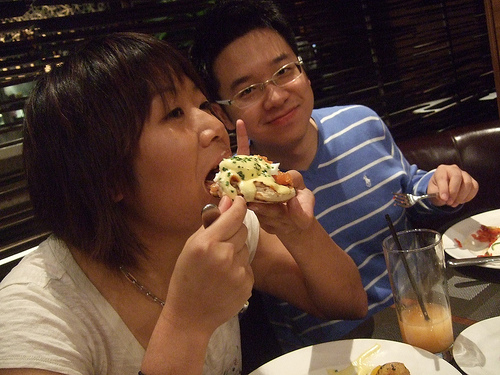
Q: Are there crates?
A: No, there are no crates.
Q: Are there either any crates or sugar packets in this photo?
A: No, there are no crates or sugar packets.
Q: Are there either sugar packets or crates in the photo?
A: No, there are no crates or sugar packets.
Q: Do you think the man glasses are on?
A: Yes, the glasses are on.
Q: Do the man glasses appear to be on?
A: Yes, the glasses are on.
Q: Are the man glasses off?
A: No, the glasses are on.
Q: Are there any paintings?
A: No, there are no paintings.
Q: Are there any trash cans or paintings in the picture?
A: No, there are no paintings or trash cans.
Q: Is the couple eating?
A: Yes, the couple is eating.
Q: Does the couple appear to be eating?
A: Yes, the couple is eating.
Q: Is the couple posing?
A: No, the couple is eating.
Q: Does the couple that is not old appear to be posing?
A: No, the couple is eating.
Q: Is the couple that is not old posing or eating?
A: The couple is eating.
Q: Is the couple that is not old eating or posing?
A: The couple is eating.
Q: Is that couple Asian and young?
A: Yes, the couple is Asian and young.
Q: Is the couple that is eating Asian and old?
A: No, the couple is Asian but young.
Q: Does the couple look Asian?
A: Yes, the couple is asian.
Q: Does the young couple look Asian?
A: Yes, the couple is asian.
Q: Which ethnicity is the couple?
A: The couple is asian.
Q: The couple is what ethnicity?
A: The couple is asian.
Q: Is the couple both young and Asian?
A: Yes, the couple is young and asian.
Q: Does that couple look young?
A: Yes, the couple is young.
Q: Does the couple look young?
A: Yes, the couple is young.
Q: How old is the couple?
A: The couple is young.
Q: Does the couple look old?
A: No, the couple is young.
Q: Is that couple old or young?
A: The couple is young.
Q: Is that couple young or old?
A: The couple is young.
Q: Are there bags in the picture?
A: No, there are no bags.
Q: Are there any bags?
A: No, there are no bags.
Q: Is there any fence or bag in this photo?
A: No, there are no bags or fences.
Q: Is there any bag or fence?
A: No, there are no bags or fences.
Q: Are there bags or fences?
A: No, there are no bags or fences.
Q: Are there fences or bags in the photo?
A: No, there are no bags or fences.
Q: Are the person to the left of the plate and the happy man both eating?
A: Yes, both the person and the man are eating.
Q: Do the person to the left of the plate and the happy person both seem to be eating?
A: Yes, both the person and the man are eating.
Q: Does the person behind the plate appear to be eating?
A: Yes, the person is eating.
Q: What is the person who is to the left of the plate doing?
A: The person is eating.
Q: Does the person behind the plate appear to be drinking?
A: No, the person is eating.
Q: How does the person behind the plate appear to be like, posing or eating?
A: The person is eating.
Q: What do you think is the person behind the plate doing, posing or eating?
A: The person is eating.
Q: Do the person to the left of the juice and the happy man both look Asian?
A: Yes, both the person and the man are asian.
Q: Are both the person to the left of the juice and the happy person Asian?
A: Yes, both the person and the man are asian.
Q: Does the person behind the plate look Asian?
A: Yes, the person is asian.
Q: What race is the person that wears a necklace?
A: The person is asian.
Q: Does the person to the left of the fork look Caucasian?
A: No, the person is asian.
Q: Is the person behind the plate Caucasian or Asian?
A: The person is asian.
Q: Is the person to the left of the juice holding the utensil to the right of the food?
A: Yes, the person is holding the fork.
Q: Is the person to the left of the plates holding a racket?
A: No, the person is holding the fork.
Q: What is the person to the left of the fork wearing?
A: The person is wearing a necklace.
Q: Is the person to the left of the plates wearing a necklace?
A: Yes, the person is wearing a necklace.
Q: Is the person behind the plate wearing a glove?
A: No, the person is wearing a necklace.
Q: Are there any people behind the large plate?
A: Yes, there is a person behind the plate.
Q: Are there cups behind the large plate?
A: No, there is a person behind the plate.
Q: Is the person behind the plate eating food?
A: Yes, the person is eating food.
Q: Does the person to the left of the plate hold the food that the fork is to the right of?
A: Yes, the person holds the food.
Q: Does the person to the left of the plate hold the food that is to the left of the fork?
A: Yes, the person holds the food.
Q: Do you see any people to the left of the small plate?
A: Yes, there is a person to the left of the plate.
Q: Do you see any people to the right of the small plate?
A: No, the person is to the left of the plate.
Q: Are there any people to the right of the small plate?
A: No, the person is to the left of the plate.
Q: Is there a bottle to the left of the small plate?
A: No, there is a person to the left of the plate.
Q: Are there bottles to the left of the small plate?
A: No, there is a person to the left of the plate.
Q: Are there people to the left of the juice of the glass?
A: Yes, there is a person to the left of the juice.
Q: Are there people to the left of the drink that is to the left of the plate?
A: Yes, there is a person to the left of the juice.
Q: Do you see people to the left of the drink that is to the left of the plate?
A: Yes, there is a person to the left of the juice.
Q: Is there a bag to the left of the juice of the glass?
A: No, there is a person to the left of the juice.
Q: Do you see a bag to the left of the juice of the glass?
A: No, there is a person to the left of the juice.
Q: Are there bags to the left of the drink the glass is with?
A: No, there is a person to the left of the juice.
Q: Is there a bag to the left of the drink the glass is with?
A: No, there is a person to the left of the juice.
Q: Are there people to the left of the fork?
A: Yes, there is a person to the left of the fork.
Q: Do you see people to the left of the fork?
A: Yes, there is a person to the left of the fork.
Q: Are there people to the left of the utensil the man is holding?
A: Yes, there is a person to the left of the fork.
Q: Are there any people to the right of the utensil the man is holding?
A: No, the person is to the left of the fork.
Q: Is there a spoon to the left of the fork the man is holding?
A: No, there is a person to the left of the fork.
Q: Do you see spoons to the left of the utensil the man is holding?
A: No, there is a person to the left of the fork.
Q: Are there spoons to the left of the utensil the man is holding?
A: No, there is a person to the left of the fork.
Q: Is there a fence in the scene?
A: No, there are no fences.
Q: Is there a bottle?
A: No, there are no bottles.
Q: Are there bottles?
A: No, there are no bottles.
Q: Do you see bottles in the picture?
A: No, there are no bottles.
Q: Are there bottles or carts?
A: No, there are no bottles or carts.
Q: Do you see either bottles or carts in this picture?
A: No, there are no bottles or carts.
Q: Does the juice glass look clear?
A: Yes, the glass is clear.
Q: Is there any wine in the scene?
A: No, there are no wines.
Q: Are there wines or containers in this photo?
A: No, there are no wines or containers.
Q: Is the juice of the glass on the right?
A: Yes, the juice is on the right of the image.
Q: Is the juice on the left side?
A: No, the juice is on the right of the image.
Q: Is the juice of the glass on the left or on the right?
A: The juice is on the right of the image.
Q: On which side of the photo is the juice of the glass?
A: The juice is on the right of the image.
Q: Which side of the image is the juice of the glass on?
A: The juice is on the right of the image.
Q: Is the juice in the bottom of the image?
A: Yes, the juice is in the bottom of the image.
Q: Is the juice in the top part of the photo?
A: No, the juice is in the bottom of the image.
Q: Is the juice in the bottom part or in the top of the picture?
A: The juice is in the bottom of the image.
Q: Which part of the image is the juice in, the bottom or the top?
A: The juice is in the bottom of the image.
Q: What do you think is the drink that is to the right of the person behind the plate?
A: The drink is juice.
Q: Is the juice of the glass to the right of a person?
A: Yes, the juice is to the right of a person.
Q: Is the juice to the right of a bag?
A: No, the juice is to the right of a person.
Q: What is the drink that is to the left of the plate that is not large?
A: The drink is juice.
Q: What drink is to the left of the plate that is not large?
A: The drink is juice.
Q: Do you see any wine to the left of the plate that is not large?
A: No, there is juice to the left of the plate.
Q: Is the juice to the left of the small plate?
A: Yes, the juice is to the left of the plate.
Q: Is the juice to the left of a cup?
A: No, the juice is to the left of the plate.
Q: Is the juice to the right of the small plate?
A: No, the juice is to the left of the plate.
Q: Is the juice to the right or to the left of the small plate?
A: The juice is to the left of the plate.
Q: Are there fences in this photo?
A: No, there are no fences.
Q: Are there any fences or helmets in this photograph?
A: No, there are no fences or helmets.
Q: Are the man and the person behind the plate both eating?
A: Yes, both the man and the person are eating.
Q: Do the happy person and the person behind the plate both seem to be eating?
A: Yes, both the man and the person are eating.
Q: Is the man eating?
A: Yes, the man is eating.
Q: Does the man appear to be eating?
A: Yes, the man is eating.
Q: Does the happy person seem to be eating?
A: Yes, the man is eating.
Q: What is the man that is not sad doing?
A: The man is eating.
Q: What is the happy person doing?
A: The man is eating.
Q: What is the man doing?
A: The man is eating.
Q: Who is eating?
A: The man is eating.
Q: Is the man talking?
A: No, the man is eating.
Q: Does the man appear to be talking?
A: No, the man is eating.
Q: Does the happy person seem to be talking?
A: No, the man is eating.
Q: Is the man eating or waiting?
A: The man is eating.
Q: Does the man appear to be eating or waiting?
A: The man is eating.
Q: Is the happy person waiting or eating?
A: The man is eating.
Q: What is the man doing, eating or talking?
A: The man is eating.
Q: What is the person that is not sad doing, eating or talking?
A: The man is eating.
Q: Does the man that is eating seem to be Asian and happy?
A: Yes, the man is Asian and happy.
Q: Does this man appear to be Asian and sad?
A: No, the man is Asian but happy.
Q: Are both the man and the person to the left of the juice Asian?
A: Yes, both the man and the person are asian.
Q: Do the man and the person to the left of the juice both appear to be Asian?
A: Yes, both the man and the person are asian.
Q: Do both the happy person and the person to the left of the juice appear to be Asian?
A: Yes, both the man and the person are asian.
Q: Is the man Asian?
A: Yes, the man is asian.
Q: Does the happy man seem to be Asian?
A: Yes, the man is asian.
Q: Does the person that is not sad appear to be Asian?
A: Yes, the man is asian.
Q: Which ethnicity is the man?
A: The man is asian.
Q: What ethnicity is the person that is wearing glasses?
A: The man is asian.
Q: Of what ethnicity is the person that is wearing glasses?
A: The man is asian.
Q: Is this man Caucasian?
A: No, the man is asian.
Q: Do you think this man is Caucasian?
A: No, the man is asian.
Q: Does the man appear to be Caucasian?
A: No, the man is asian.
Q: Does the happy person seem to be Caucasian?
A: No, the man is asian.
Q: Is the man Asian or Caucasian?
A: The man is asian.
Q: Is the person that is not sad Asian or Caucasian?
A: The man is asian.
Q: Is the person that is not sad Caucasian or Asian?
A: The man is asian.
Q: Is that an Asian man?
A: Yes, that is an Asian man.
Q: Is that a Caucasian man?
A: No, that is an Asian man.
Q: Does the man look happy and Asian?
A: Yes, the man is happy and asian.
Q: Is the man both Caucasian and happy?
A: No, the man is happy but asian.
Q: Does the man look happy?
A: Yes, the man is happy.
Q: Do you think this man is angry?
A: No, the man is happy.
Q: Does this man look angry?
A: No, the man is happy.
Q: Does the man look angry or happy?
A: The man is happy.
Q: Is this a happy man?
A: Yes, this is a happy man.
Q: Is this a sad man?
A: No, this is a happy man.